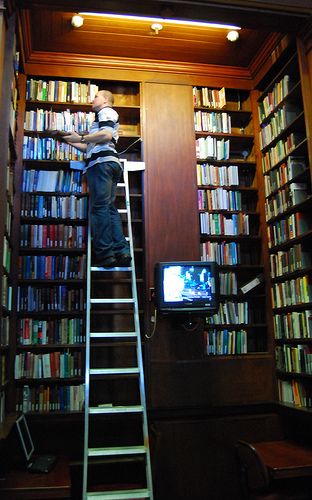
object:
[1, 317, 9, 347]
book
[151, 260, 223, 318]
tv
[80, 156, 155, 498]
ladder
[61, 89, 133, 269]
man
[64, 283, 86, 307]
book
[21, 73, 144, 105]
book shelf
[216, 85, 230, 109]
book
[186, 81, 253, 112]
book shelf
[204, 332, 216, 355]
book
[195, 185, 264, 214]
book shelf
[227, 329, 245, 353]
book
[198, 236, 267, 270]
book shelf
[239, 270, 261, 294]
book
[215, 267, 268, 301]
book shelf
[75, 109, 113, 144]
left arm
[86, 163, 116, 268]
leg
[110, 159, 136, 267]
leg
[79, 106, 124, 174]
shirt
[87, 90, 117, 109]
head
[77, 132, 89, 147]
left wrist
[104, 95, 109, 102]
left ear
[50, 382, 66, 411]
book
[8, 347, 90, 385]
bookshelf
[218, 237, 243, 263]
book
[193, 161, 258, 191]
bookshelf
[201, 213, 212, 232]
book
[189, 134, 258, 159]
bookshelf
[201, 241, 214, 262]
book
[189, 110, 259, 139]
bookshelf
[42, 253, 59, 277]
book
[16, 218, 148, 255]
bookshelf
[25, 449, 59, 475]
keyboard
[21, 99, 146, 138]
on shelf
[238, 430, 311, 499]
desk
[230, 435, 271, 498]
desk chair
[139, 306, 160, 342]
t.v. cable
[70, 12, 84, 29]
light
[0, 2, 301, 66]
ceiling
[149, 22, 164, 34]
light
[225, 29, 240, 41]
light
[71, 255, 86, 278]
book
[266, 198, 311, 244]
shelf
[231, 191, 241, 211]
book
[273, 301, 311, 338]
shelf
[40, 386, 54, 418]
book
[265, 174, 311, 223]
shelf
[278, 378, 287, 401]
book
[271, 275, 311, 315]
shelf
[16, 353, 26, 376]
book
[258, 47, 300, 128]
shelf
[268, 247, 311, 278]
shelf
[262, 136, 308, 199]
shelf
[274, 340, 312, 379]
shelf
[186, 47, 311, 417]
shelves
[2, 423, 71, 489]
desk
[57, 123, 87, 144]
in his hand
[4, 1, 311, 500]
shelves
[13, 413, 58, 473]
computer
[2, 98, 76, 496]
table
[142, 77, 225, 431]
wall